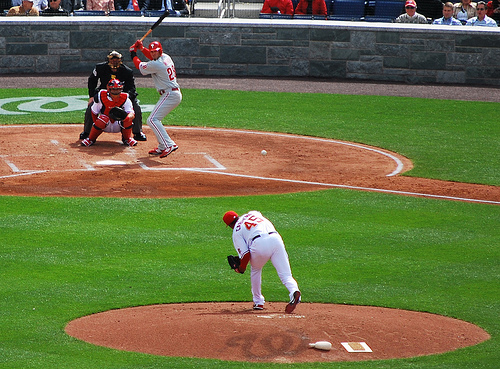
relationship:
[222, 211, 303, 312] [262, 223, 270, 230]
pitcher wearing white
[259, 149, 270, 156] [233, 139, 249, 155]
baseball in air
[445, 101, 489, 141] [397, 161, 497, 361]
grass on field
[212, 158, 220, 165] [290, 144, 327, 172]
white lines on dirt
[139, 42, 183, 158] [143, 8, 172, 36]
player holding bat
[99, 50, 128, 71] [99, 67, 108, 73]
umpire wearing black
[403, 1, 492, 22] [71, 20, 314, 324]
spectators watching game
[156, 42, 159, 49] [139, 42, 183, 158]
red helmet on batter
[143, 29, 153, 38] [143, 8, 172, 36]
brown and black bat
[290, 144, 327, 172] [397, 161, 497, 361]
dirt on field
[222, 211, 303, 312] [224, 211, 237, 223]
man with hat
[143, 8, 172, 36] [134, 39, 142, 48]
bat in hand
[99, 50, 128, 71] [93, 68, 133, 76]
umpire wearing black clothes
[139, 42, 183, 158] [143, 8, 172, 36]
player about to swing bat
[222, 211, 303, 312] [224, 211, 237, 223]
pitcher wears red hat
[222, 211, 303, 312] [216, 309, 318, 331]
pitcher on mound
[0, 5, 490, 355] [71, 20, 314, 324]
photo taken at game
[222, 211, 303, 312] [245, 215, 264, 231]
pitcher number 45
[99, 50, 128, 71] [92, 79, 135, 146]
umpire behind catcher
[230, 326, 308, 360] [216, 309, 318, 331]
w on mound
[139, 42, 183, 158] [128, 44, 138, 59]
batter right handed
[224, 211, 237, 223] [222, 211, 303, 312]
red hat on pitcher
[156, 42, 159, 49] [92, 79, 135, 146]
red helmet on catcher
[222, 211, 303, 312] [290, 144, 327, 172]
pitcher's mound od dirt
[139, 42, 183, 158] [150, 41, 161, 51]
batter has red hat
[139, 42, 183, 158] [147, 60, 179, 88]
batter wears gray shirt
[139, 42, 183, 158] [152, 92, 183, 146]
batter wears gray pants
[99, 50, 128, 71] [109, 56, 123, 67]
umpire wearing a mask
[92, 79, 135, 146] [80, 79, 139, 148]
catcher has red chest catcher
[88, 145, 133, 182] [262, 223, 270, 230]
home plate white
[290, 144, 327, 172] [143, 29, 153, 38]
dirt reddh brown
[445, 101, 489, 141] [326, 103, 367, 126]
grass short and green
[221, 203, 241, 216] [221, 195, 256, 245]
hat on head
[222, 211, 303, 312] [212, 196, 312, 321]
guy bending over in uniform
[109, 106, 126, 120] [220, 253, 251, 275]
mitt in hand